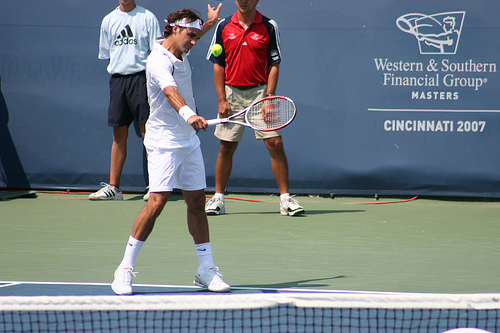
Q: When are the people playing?
A: Now.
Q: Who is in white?
A: A man.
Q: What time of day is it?
A: Daytime.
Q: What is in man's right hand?
A: Racquet.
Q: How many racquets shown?
A: One.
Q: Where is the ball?
A: In air.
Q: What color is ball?
A: Yellow.